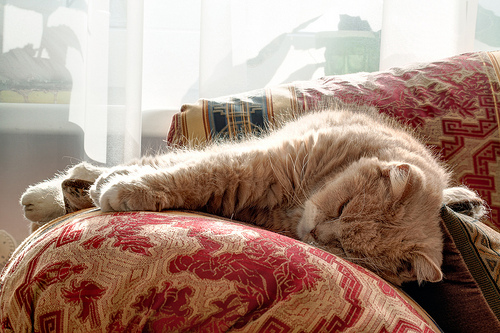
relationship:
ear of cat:
[391, 163, 420, 210] [70, 133, 452, 287]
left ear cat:
[412, 250, 443, 283] [70, 133, 452, 287]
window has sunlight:
[48, 18, 106, 61] [45, 43, 73, 94]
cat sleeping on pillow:
[70, 133, 452, 287] [448, 224, 488, 316]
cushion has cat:
[166, 48, 499, 234] [70, 133, 452, 287]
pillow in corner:
[448, 224, 488, 316] [480, 184, 495, 203]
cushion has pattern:
[166, 48, 499, 234] [450, 100, 484, 144]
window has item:
[48, 18, 106, 61] [38, 97, 55, 120]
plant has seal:
[295, 28, 361, 50] [331, 52, 361, 68]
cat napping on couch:
[70, 133, 452, 287] [26, 229, 260, 330]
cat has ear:
[70, 133, 452, 287] [391, 163, 420, 210]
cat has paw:
[70, 133, 452, 287] [17, 186, 48, 226]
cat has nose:
[70, 133, 452, 287] [312, 215, 331, 244]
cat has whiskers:
[70, 133, 452, 287] [276, 164, 305, 203]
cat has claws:
[70, 133, 452, 287] [124, 202, 134, 212]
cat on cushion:
[70, 133, 452, 287] [166, 48, 499, 234]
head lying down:
[304, 150, 445, 289] [353, 228, 456, 289]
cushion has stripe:
[166, 48, 499, 234] [229, 101, 262, 127]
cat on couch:
[70, 133, 452, 287] [26, 229, 260, 330]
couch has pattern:
[26, 229, 260, 330] [450, 100, 484, 144]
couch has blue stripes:
[26, 229, 260, 330] [209, 101, 225, 131]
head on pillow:
[304, 150, 445, 289] [448, 224, 488, 316]